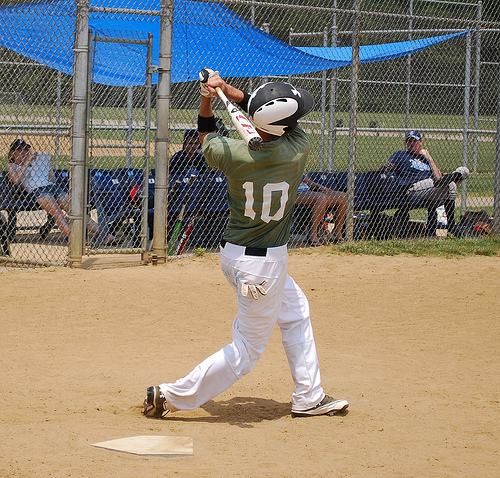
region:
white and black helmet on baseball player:
[239, 75, 324, 145]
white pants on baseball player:
[141, 233, 351, 433]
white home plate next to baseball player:
[83, 425, 204, 471]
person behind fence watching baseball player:
[2, 133, 133, 253]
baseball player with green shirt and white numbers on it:
[198, 121, 338, 254]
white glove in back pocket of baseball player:
[226, 270, 272, 305]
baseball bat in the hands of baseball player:
[191, 63, 270, 160]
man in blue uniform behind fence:
[373, 123, 495, 246]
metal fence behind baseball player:
[1, 7, 499, 280]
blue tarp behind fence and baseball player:
[1, 5, 477, 91]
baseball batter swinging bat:
[139, 58, 356, 421]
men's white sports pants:
[160, 233, 330, 432]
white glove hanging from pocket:
[235, 275, 272, 302]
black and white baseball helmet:
[240, 79, 320, 141]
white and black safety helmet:
[244, 78, 315, 137]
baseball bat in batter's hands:
[195, 67, 265, 155]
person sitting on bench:
[372, 128, 474, 240]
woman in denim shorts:
[4, 134, 123, 255]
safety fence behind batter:
[0, 3, 498, 280]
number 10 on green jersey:
[240, 178, 290, 226]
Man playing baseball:
[143, 67, 350, 419]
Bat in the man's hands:
[211, 84, 265, 151]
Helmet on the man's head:
[245, 79, 315, 136]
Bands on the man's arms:
[196, 92, 252, 134]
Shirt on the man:
[201, 127, 312, 249]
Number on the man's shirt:
[241, 179, 289, 224]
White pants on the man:
[156, 242, 326, 413]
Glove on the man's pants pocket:
[240, 278, 270, 300]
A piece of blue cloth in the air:
[0, 1, 472, 88]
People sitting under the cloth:
[6, 120, 471, 246]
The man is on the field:
[140, 41, 369, 432]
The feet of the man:
[126, 380, 351, 432]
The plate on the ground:
[90, 425, 197, 465]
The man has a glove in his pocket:
[233, 276, 278, 301]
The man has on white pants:
[158, 237, 328, 415]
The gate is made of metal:
[320, 15, 486, 237]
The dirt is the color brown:
[352, 298, 474, 459]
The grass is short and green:
[348, 232, 496, 257]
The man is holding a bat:
[196, 60, 268, 163]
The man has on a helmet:
[245, 76, 321, 141]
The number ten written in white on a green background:
[233, 171, 288, 228]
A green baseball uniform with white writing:
[198, 129, 310, 244]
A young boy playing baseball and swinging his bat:
[174, 55, 350, 426]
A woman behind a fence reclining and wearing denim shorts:
[11, 133, 90, 251]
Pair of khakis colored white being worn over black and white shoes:
[210, 226, 357, 418]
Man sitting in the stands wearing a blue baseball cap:
[381, 117, 467, 237]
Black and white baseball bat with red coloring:
[196, 64, 262, 156]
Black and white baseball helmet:
[242, 72, 311, 146]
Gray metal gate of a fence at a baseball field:
[67, 3, 174, 267]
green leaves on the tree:
[388, 54, 433, 91]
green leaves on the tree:
[469, 46, 499, 89]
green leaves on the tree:
[15, 56, 40, 88]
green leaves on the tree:
[405, 56, 458, 118]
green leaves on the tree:
[449, 25, 457, 42]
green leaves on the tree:
[452, 11, 487, 53]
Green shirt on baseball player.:
[201, 125, 311, 247]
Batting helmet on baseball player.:
[246, 80, 314, 137]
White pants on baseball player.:
[158, 237, 325, 412]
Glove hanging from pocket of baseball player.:
[240, 279, 267, 299]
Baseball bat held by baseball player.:
[214, 85, 264, 151]